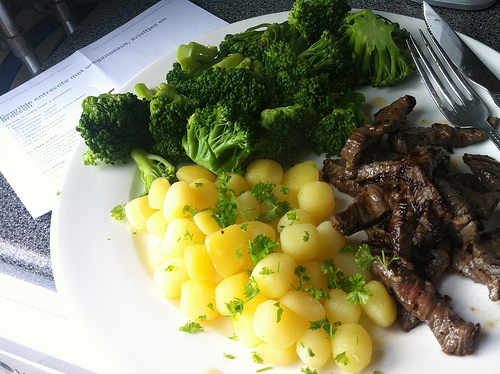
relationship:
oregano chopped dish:
[126, 155, 395, 371] [47, 5, 498, 370]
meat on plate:
[373, 258, 479, 357] [79, 259, 154, 325]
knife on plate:
[419, 0, 499, 109] [36, 9, 484, 365]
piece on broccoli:
[178, 102, 253, 177] [78, 2, 419, 178]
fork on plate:
[404, 26, 499, 153] [36, 9, 484, 365]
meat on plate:
[318, 94, 498, 355] [36, 9, 484, 365]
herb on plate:
[243, 231, 286, 271] [36, 9, 484, 365]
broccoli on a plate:
[183, 103, 250, 178] [36, 9, 484, 365]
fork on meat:
[404, 26, 489, 135] [420, 113, 492, 145]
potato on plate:
[253, 298, 307, 347] [36, 9, 484, 365]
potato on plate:
[250, 295, 314, 349] [36, 9, 484, 365]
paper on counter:
[0, 0, 232, 221] [20, 242, 48, 288]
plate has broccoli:
[57, 212, 112, 289] [183, 103, 250, 178]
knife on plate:
[419, 0, 499, 109] [58, 225, 136, 303]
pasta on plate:
[191, 251, 287, 322] [36, 9, 484, 365]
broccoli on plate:
[177, 102, 250, 180] [63, 214, 118, 304]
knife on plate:
[419, 0, 484, 94] [36, 9, 484, 365]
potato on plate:
[277, 220, 321, 258] [36, 9, 484, 365]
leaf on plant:
[183, 321, 204, 333] [50, 8, 497, 372]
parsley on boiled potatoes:
[340, 273, 372, 305] [231, 162, 388, 359]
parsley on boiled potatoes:
[340, 270, 365, 303] [231, 162, 388, 359]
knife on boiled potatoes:
[419, 0, 499, 109] [231, 162, 388, 359]